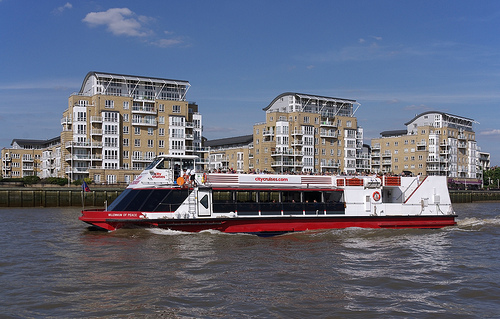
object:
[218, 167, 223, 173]
people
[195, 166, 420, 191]
upper deck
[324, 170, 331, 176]
people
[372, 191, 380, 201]
life ring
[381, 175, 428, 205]
staircase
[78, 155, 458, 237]
boat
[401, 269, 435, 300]
water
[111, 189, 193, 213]
window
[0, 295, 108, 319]
water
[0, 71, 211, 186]
building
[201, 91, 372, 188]
building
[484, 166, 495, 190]
bush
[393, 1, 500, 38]
sky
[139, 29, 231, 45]
sky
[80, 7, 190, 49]
cloud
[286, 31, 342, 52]
sky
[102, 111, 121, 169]
windows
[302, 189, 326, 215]
windows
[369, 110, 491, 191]
building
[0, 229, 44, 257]
water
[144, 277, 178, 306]
water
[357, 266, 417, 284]
waves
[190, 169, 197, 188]
people